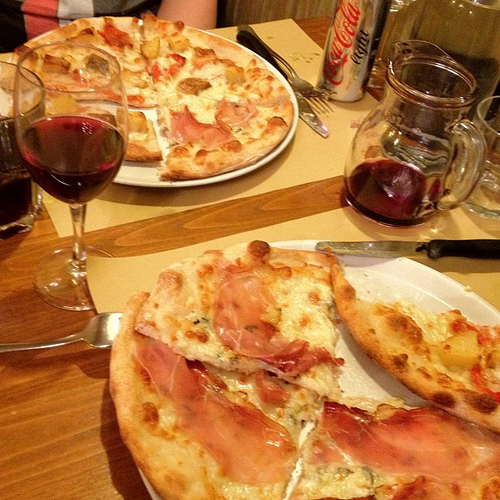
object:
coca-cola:
[315, 0, 395, 102]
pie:
[132, 241, 332, 406]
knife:
[317, 237, 497, 262]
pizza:
[1, 15, 293, 180]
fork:
[0, 312, 122, 354]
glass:
[2, 63, 46, 240]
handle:
[437, 117, 494, 221]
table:
[0, 13, 500, 495]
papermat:
[0, 17, 394, 240]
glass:
[12, 38, 128, 314]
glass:
[347, 43, 488, 228]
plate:
[21, 16, 300, 190]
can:
[312, 0, 389, 102]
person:
[15, 1, 223, 41]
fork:
[235, 21, 328, 98]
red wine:
[18, 117, 125, 207]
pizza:
[326, 247, 499, 440]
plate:
[107, 237, 500, 497]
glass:
[463, 94, 500, 218]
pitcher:
[0, 0, 500, 500]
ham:
[111, 290, 297, 500]